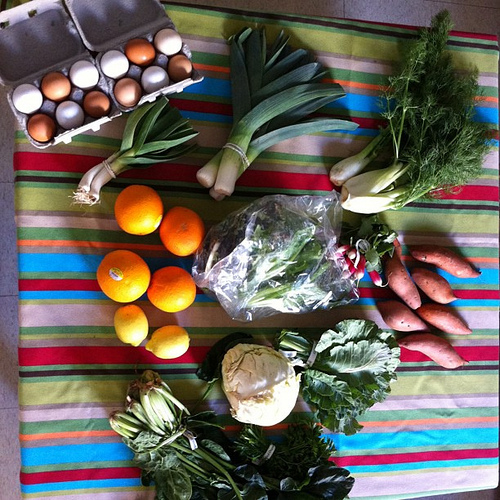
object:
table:
[11, 1, 500, 500]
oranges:
[96, 184, 206, 313]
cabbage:
[220, 342, 302, 426]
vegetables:
[66, 7, 496, 500]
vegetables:
[200, 195, 353, 314]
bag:
[191, 188, 360, 323]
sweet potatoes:
[376, 245, 483, 370]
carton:
[0, 0, 204, 150]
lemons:
[113, 304, 191, 360]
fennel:
[195, 25, 360, 202]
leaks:
[67, 93, 202, 211]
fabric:
[12, 4, 500, 499]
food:
[10, 7, 498, 500]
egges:
[12, 28, 193, 143]